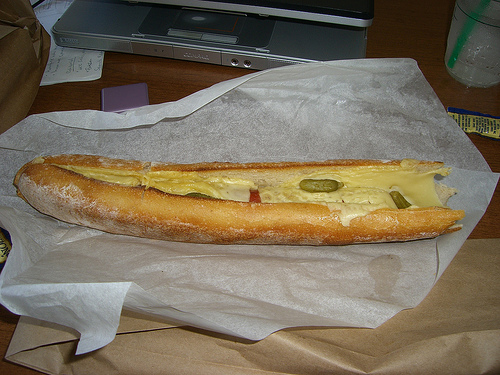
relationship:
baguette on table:
[12, 154, 466, 249] [107, 57, 211, 102]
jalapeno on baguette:
[293, 175, 347, 195] [12, 154, 466, 249]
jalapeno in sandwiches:
[293, 175, 347, 195] [21, 146, 461, 218]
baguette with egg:
[12, 149, 466, 247] [330, 185, 411, 219]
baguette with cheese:
[12, 149, 466, 247] [168, 163, 226, 189]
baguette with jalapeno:
[12, 149, 466, 247] [293, 175, 347, 195]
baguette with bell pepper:
[12, 149, 466, 247] [235, 190, 266, 208]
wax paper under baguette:
[0, 65, 498, 348] [12, 154, 466, 249]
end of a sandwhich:
[13, 155, 90, 229] [13, 152, 465, 245]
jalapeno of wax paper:
[293, 175, 347, 195] [0, 65, 498, 348]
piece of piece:
[101, 81, 153, 110] [93, 81, 153, 116]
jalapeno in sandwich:
[292, 175, 356, 198] [5, 134, 467, 258]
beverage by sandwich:
[435, 1, 499, 93] [5, 134, 467, 258]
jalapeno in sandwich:
[293, 175, 347, 195] [51, 152, 441, 242]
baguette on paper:
[12, 154, 466, 249] [169, 57, 340, 120]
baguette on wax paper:
[12, 154, 466, 249] [0, 57, 499, 359]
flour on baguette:
[30, 189, 39, 199] [12, 154, 466, 249]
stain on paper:
[369, 247, 409, 307] [21, 245, 325, 310]